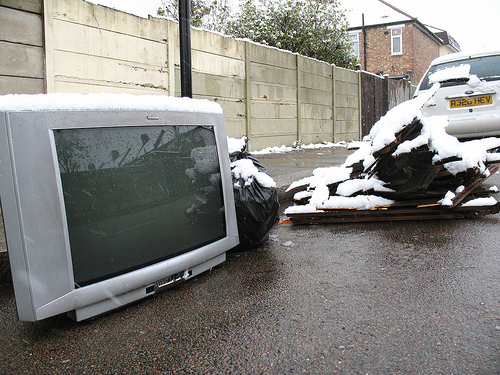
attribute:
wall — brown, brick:
[356, 23, 408, 80]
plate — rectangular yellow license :
[446, 92, 484, 106]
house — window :
[386, 21, 407, 61]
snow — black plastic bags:
[227, 137, 274, 202]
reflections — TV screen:
[24, 105, 239, 288]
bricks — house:
[347, 19, 439, 89]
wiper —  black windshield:
[422, 54, 484, 84]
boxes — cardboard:
[281, 92, 499, 216]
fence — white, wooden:
[159, 35, 376, 152]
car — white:
[399, 46, 483, 141]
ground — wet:
[1, 147, 499, 370]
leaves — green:
[153, 2, 356, 72]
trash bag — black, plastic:
[222, 127, 298, 263]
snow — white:
[222, 127, 278, 190]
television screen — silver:
[4, 87, 249, 337]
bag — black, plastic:
[235, 136, 285, 263]